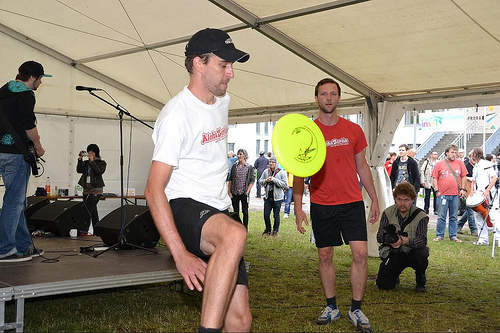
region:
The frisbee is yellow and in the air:
[247, 77, 368, 220]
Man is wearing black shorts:
[158, 170, 246, 254]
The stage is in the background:
[4, 192, 212, 321]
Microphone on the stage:
[68, 65, 167, 233]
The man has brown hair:
[307, 73, 347, 109]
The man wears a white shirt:
[154, 88, 241, 214]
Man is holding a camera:
[379, 160, 441, 290]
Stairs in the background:
[420, 118, 483, 158]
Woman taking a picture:
[65, 123, 116, 229]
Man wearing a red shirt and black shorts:
[288, 78, 388, 254]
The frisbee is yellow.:
[254, 92, 322, 184]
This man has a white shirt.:
[158, 84, 249, 219]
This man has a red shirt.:
[310, 115, 370, 209]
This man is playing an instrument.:
[3, 50, 50, 267]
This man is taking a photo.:
[368, 166, 442, 293]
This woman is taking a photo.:
[58, 134, 118, 230]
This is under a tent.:
[13, 15, 478, 317]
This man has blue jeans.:
[8, 150, 33, 274]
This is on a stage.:
[3, 170, 161, 317]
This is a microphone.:
[68, 70, 155, 225]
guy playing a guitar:
[2, 55, 49, 274]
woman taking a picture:
[72, 142, 112, 224]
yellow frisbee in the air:
[267, 110, 328, 184]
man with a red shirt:
[298, 85, 378, 325]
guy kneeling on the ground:
[376, 181, 433, 292]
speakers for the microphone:
[35, 200, 96, 244]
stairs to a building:
[427, 126, 490, 146]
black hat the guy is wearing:
[172, 28, 253, 56]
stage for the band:
[26, 275, 99, 299]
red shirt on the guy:
[434, 167, 461, 195]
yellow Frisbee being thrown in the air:
[263, 108, 327, 178]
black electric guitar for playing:
[15, 125, 42, 179]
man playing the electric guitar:
[0, 53, 55, 267]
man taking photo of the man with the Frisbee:
[371, 183, 436, 297]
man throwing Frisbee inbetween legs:
[143, 23, 327, 330]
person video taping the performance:
[69, 138, 105, 235]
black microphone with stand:
[73, 81, 150, 263]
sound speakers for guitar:
[95, 197, 155, 259]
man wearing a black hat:
[178, 24, 253, 101]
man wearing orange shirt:
[278, 74, 393, 236]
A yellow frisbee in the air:
[273, 110, 325, 183]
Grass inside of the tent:
[396, 294, 490, 329]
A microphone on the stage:
[74, 82, 101, 94]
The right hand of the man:
[174, 256, 209, 289]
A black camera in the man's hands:
[379, 226, 396, 243]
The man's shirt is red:
[331, 155, 355, 193]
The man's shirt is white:
[188, 154, 216, 194]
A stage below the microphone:
[23, 270, 160, 301]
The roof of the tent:
[293, 13, 482, 67]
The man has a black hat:
[187, 29, 247, 58]